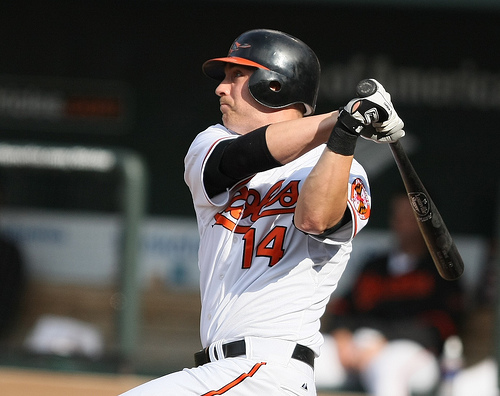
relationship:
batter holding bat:
[116, 28, 408, 394] [356, 79, 466, 283]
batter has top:
[116, 28, 408, 394] [182, 123, 372, 347]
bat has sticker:
[356, 79, 466, 283] [410, 190, 432, 220]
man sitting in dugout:
[313, 195, 462, 394] [0, 0, 495, 394]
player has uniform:
[116, 28, 409, 393] [119, 124, 372, 394]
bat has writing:
[356, 79, 466, 283] [407, 189, 432, 222]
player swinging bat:
[116, 28, 409, 393] [356, 79, 466, 283]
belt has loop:
[195, 339, 313, 367] [209, 343, 224, 362]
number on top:
[240, 225, 290, 268] [182, 123, 372, 347]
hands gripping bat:
[339, 79, 406, 144] [356, 79, 466, 283]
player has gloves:
[116, 28, 409, 393] [327, 79, 406, 157]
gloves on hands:
[327, 79, 406, 157] [339, 79, 406, 144]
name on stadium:
[322, 52, 499, 110] [0, 1, 498, 236]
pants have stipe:
[117, 337, 316, 395] [200, 360, 269, 394]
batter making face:
[116, 28, 408, 394] [215, 66, 248, 132]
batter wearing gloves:
[116, 28, 408, 394] [327, 79, 406, 157]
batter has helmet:
[116, 28, 408, 394] [202, 28, 321, 118]